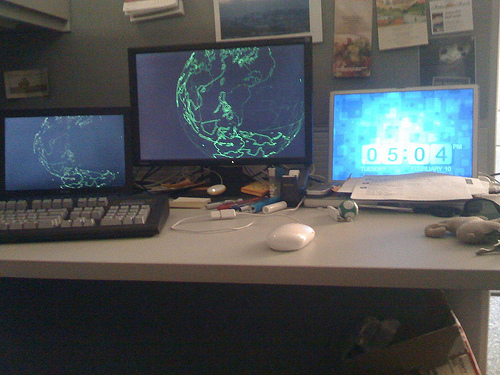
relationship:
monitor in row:
[3, 105, 145, 203] [3, 35, 482, 193]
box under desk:
[325, 282, 463, 369] [3, 175, 497, 288]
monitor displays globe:
[3, 105, 145, 203] [28, 114, 121, 188]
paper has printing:
[337, 163, 481, 212] [358, 176, 411, 198]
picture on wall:
[207, 1, 325, 48] [2, 5, 488, 161]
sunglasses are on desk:
[413, 193, 498, 223] [3, 175, 497, 288]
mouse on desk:
[262, 215, 321, 256] [3, 175, 497, 288]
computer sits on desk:
[326, 84, 483, 194] [3, 175, 497, 288]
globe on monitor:
[28, 114, 121, 188] [3, 105, 145, 203]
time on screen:
[355, 138, 458, 173] [334, 95, 471, 175]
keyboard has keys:
[2, 186, 172, 246] [3, 195, 154, 234]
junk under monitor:
[172, 165, 310, 218] [124, 43, 318, 165]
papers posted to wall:
[120, 1, 483, 82] [2, 5, 488, 161]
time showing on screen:
[355, 138, 458, 173] [334, 95, 471, 175]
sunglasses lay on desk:
[413, 193, 498, 223] [3, 175, 497, 288]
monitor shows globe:
[3, 105, 145, 203] [28, 114, 121, 188]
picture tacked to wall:
[207, 1, 325, 48] [2, 5, 488, 161]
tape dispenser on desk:
[276, 165, 310, 212] [3, 175, 497, 288]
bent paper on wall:
[117, 2, 188, 30] [2, 5, 488, 161]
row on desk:
[3, 35, 482, 193] [3, 175, 497, 288]